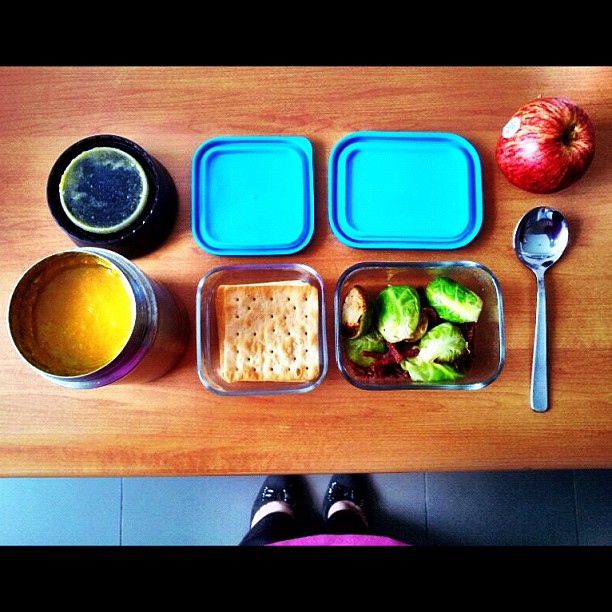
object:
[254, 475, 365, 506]
shoes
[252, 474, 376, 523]
feet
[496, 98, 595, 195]
apple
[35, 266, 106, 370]
cheese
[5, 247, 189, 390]
container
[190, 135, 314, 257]
lid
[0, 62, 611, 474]
board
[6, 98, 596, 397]
food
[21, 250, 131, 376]
soup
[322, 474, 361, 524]
dress shoe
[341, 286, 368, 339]
brussels sprout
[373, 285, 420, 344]
brussels sprout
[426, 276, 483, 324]
brussels sprout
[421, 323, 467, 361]
brussels sprout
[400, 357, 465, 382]
brussels sprout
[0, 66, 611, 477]
table top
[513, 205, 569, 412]
spoon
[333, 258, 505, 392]
bowl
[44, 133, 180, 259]
cover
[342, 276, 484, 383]
sprouts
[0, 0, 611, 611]
room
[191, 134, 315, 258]
lids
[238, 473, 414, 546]
person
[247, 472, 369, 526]
shoes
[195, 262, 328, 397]
container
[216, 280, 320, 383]
cracker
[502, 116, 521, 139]
sticker